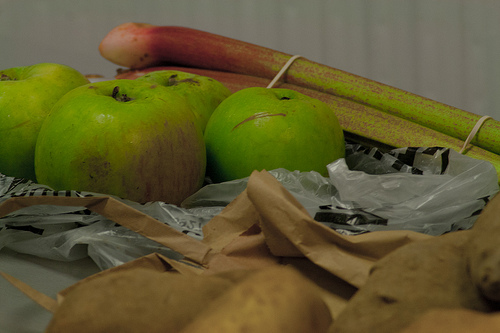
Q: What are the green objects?
A: Apples.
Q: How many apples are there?
A: Four.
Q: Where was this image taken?
A: In a house.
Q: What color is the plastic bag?
A: Gray.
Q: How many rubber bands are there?
A: Two.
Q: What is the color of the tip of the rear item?
A: Red.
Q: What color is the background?
A: White.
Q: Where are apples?
A: On a table.